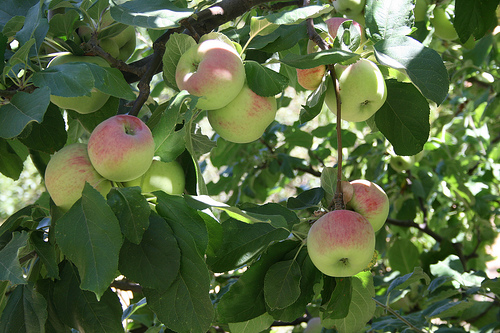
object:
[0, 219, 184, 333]
branch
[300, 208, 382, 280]
apples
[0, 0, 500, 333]
tree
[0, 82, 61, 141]
leaves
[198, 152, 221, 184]
sun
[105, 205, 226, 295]
foilage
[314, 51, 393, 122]
fruits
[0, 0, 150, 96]
branch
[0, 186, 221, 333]
shadows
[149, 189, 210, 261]
leaf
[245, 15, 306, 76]
blossom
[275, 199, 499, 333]
branches